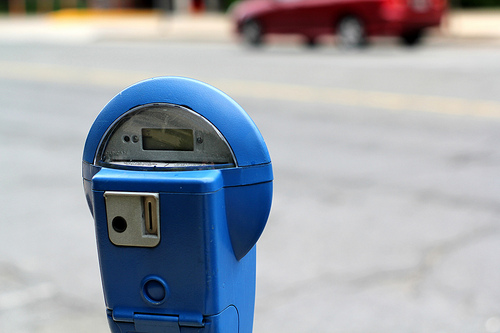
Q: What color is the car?
A: Red.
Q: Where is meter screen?
A: Behind glass.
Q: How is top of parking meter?
A: Rounded.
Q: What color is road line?
A: Yellow.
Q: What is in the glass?
A: Reflection.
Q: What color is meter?
A: Blue.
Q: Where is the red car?
A: Background.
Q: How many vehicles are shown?
A: One.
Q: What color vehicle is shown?
A: Red.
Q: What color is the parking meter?
A: Blue.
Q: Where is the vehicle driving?
A: Street.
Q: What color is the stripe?
A: Yellow.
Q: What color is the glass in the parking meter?
A: Clear.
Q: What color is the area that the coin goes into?
A: Silver.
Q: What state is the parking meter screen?
A: Blank.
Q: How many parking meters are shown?
A: One.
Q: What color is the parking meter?
A: Blue.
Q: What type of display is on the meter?
A: Digital.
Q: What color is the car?
A: Red.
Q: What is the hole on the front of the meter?
A: Coin slot.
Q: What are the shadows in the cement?
A: Concrete.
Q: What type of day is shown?
A: Sunny.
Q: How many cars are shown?
A: One.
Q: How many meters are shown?
A: One.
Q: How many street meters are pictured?
A: 1.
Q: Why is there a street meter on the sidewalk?
A: To pay for parking.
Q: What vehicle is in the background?
A: A car.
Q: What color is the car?
A: Red.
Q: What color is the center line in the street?
A: Yellow.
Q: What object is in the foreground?
A: A parking meter.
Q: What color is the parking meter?
A: Blue.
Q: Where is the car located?
A: Across the street.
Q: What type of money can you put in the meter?
A: Coins.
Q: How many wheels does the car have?
A: Four.